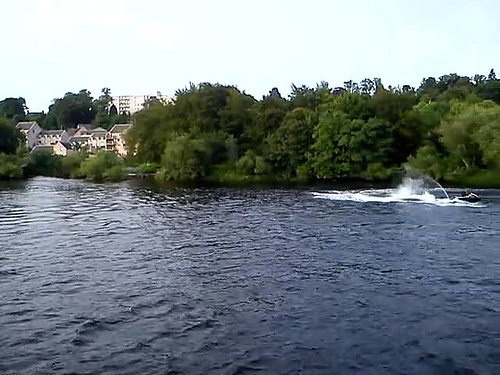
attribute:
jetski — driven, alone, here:
[340, 151, 467, 203]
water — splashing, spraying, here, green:
[64, 175, 407, 356]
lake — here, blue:
[75, 209, 442, 360]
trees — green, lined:
[133, 73, 365, 162]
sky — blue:
[261, 11, 468, 59]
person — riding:
[448, 188, 475, 212]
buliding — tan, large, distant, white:
[40, 106, 154, 155]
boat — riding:
[342, 144, 495, 236]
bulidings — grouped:
[5, 72, 163, 178]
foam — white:
[319, 176, 451, 209]